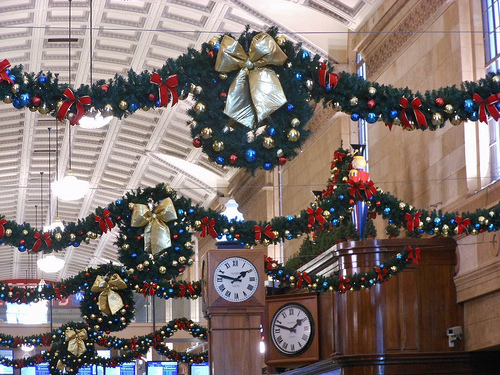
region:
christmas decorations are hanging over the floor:
[8, 22, 497, 358]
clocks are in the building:
[213, 252, 320, 362]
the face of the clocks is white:
[210, 255, 310, 355]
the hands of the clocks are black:
[211, 255, 312, 357]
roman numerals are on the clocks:
[212, 252, 312, 355]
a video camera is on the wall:
[441, 320, 471, 356]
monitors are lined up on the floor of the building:
[5, 345, 207, 374]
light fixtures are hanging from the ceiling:
[26, 103, 113, 289]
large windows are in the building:
[211, 107, 498, 257]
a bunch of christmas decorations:
[52, 52, 286, 257]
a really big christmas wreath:
[185, 35, 306, 162]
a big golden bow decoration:
[215, 18, 295, 115]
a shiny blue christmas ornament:
[243, 142, 256, 159]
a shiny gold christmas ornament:
[256, 131, 273, 151]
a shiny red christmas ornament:
[220, 142, 243, 163]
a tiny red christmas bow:
[390, 97, 425, 128]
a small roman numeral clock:
[201, 265, 277, 312]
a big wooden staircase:
[315, 248, 456, 364]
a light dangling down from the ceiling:
[54, 148, 102, 205]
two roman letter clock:
[218, 255, 325, 355]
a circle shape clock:
[263, 306, 329, 364]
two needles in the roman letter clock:
[278, 316, 306, 342]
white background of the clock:
[278, 310, 305, 349]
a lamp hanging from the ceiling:
[47, 140, 94, 204]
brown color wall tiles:
[383, 115, 447, 187]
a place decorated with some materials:
[18, 209, 199, 368]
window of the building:
[458, 60, 498, 170]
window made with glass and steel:
[476, 61, 499, 152]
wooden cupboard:
[206, 249, 438, 374]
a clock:
[211, 259, 262, 303]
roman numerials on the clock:
[275, 331, 289, 348]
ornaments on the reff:
[211, 133, 235, 160]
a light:
[49, 177, 91, 202]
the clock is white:
[213, 262, 257, 302]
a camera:
[443, 324, 466, 349]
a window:
[482, 14, 499, 44]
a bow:
[206, 39, 291, 129]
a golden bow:
[213, 37, 298, 129]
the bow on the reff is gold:
[88, 274, 128, 311]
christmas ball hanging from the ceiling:
[326, 70, 471, 157]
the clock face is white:
[255, 287, 322, 369]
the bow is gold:
[206, 9, 291, 136]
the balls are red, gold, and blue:
[334, 70, 395, 138]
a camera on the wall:
[412, 302, 474, 352]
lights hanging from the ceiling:
[24, 57, 119, 212]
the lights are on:
[20, 73, 124, 260]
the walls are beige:
[365, 25, 482, 205]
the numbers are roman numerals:
[204, 251, 258, 310]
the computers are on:
[89, 345, 206, 374]